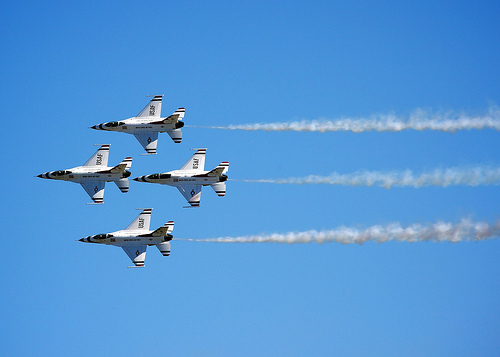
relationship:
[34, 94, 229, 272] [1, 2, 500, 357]
jets in sky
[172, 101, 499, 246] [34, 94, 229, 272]
trails behind jets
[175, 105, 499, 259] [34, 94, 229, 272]
trails behind jets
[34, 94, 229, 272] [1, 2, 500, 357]
jets on sky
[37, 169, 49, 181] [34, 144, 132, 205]
nose of jet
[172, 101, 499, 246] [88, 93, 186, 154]
trails behind jet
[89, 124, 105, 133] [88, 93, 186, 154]
nose of jet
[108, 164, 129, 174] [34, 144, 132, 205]
rudder of jet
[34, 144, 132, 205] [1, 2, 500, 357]
jet in sky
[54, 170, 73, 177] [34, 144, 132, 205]
cockpit of jet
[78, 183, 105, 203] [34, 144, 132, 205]
wing of jet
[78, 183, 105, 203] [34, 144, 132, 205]
wing on jet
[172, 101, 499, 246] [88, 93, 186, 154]
trails of jet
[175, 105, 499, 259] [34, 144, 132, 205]
trails behind jet